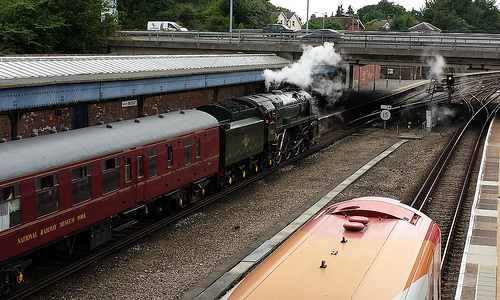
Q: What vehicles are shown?
A: Trains.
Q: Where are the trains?
A: On tracks.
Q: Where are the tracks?
A: At a train station.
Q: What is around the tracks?
A: Gravel.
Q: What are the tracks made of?
A: Metal.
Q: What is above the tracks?
A: A bridge.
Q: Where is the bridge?
A: Above the tracks.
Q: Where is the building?
A: Beside the trains.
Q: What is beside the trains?
A: A building.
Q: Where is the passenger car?
A: On the track near the platform.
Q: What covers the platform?
A: A metal roof.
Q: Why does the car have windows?
A: Passengers like to see out.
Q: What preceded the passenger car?
A: A coal car, preceded by a steam engine.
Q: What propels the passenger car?
A: A steam engine.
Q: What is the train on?
A: Tracks.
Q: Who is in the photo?
A: No one.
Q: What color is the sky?
A: White.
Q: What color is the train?
A: Red and black.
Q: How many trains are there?
A: Two.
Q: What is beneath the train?
A: Tracks.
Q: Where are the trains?
A: At a train depot.